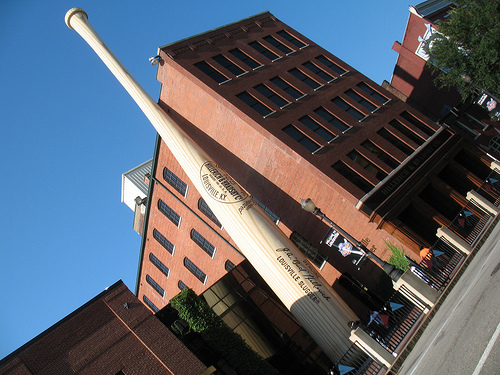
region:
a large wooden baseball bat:
[61, 3, 376, 372]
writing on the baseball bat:
[271, 239, 337, 310]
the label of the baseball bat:
[195, 155, 254, 210]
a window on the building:
[278, 118, 327, 158]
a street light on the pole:
[293, 189, 323, 224]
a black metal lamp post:
[309, 203, 404, 283]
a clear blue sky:
[1, 0, 428, 362]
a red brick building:
[0, 276, 220, 373]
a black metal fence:
[321, 160, 497, 373]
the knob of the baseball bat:
[62, 3, 90, 32]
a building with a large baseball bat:
[40, 23, 438, 347]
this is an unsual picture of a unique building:
[33, 8, 441, 360]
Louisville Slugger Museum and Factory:
[65, 38, 464, 348]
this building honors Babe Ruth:
[63, 15, 366, 347]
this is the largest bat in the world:
[56, 8, 381, 358]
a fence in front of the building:
[242, 186, 492, 358]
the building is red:
[27, 160, 302, 325]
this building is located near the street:
[165, 35, 475, 292]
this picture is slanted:
[8, 10, 445, 371]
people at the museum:
[388, 211, 458, 289]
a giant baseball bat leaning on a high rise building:
[61, 6, 373, 372]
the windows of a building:
[260, 25, 307, 60]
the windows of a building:
[146, 197, 186, 279]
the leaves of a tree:
[439, 34, 497, 82]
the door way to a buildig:
[394, 202, 452, 244]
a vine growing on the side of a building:
[174, 297, 256, 372]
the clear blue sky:
[15, 84, 66, 158]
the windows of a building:
[274, 60, 349, 130]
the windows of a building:
[146, 236, 206, 285]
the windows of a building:
[372, 107, 427, 152]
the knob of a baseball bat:
[58, 3, 93, 33]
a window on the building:
[185, 223, 220, 261]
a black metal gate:
[317, 160, 498, 374]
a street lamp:
[292, 191, 327, 221]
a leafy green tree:
[415, 0, 497, 112]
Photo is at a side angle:
[1, 2, 498, 367]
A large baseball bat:
[60, 5, 386, 373]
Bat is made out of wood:
[55, 0, 358, 372]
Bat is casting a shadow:
[152, 93, 409, 325]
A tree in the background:
[415, 0, 497, 112]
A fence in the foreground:
[337, 165, 497, 371]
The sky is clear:
[0, 0, 415, 360]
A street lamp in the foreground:
[295, 191, 401, 282]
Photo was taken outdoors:
[5, 0, 497, 371]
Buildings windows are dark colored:
[132, 21, 437, 329]